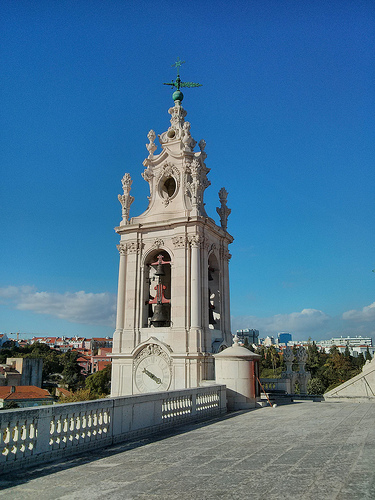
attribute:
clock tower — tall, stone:
[108, 99, 232, 390]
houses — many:
[0, 327, 372, 455]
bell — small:
[141, 256, 173, 288]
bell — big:
[121, 292, 181, 337]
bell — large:
[143, 249, 186, 319]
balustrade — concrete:
[0, 385, 230, 469]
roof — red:
[1, 384, 49, 402]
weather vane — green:
[155, 65, 200, 100]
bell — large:
[146, 301, 168, 325]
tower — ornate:
[107, 53, 235, 395]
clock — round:
[128, 339, 175, 400]